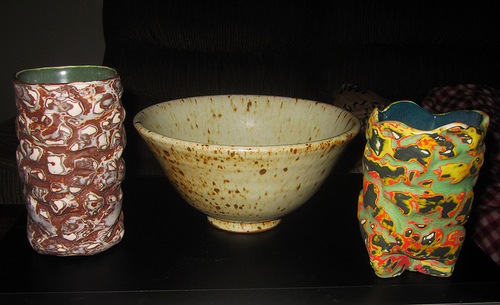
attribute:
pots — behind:
[32, 57, 406, 253]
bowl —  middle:
[132, 95, 359, 232]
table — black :
[19, 183, 496, 299]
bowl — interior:
[131, 61, 353, 256]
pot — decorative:
[357, 100, 490, 275]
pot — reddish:
[13, 58, 127, 258]